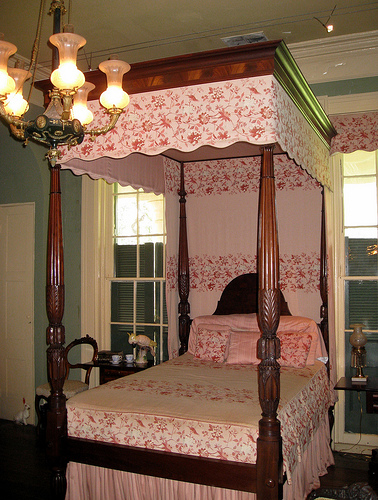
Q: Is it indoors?
A: Yes, it is indoors.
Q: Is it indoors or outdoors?
A: It is indoors.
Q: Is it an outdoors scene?
A: No, it is indoors.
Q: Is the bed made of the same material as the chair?
A: Yes, both the bed and the chair are made of wood.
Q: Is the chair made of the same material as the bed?
A: Yes, both the chair and the bed are made of wood.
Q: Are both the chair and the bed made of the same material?
A: Yes, both the chair and the bed are made of wood.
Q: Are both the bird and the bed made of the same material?
A: No, the bird is made of glass and the bed is made of wood.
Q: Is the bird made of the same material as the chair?
A: No, the bird is made of glass and the chair is made of wood.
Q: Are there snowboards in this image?
A: No, there are no snowboards.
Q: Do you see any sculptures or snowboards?
A: No, there are no snowboards or sculptures.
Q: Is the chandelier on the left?
A: Yes, the chandelier is on the left of the image.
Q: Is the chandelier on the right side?
A: No, the chandelier is on the left of the image.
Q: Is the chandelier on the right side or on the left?
A: The chandelier is on the left of the image.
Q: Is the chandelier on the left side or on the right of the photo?
A: The chandelier is on the left of the image.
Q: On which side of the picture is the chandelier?
A: The chandelier is on the left of the image.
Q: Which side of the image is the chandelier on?
A: The chandelier is on the left of the image.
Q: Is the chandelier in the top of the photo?
A: Yes, the chandelier is in the top of the image.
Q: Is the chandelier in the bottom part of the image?
A: No, the chandelier is in the top of the image.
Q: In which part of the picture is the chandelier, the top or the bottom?
A: The chandelier is in the top of the image.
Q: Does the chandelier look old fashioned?
A: Yes, the chandelier is old fashioned.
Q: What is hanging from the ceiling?
A: The chandelier is hanging from the ceiling.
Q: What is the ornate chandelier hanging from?
A: The chandelier is hanging from the ceiling.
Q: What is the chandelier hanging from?
A: The chandelier is hanging from the ceiling.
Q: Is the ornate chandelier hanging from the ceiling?
A: Yes, the chandelier is hanging from the ceiling.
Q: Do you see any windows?
A: Yes, there is a window.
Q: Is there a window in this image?
A: Yes, there is a window.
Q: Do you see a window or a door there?
A: Yes, there is a window.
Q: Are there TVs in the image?
A: No, there are no tvs.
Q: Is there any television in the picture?
A: No, there are no televisions.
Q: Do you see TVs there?
A: No, there are no tvs.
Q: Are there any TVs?
A: No, there are no tvs.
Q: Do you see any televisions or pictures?
A: No, there are no televisions or pictures.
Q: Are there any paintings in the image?
A: No, there are no paintings.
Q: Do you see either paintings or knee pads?
A: No, there are no paintings or knee pads.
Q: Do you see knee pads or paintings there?
A: No, there are no paintings or knee pads.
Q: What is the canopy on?
A: The canopy is on the bed.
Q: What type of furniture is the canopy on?
A: The canopy is on the bed.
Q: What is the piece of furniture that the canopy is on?
A: The piece of furniture is a bed.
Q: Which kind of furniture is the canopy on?
A: The canopy is on the bed.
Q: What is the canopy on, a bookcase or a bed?
A: The canopy is on a bed.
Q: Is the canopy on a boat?
A: No, the canopy is on a bed.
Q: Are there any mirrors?
A: No, there are no mirrors.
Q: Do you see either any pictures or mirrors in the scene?
A: No, there are no mirrors or pictures.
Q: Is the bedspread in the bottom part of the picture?
A: Yes, the bedspread is in the bottom of the image.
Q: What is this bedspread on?
A: The bedspread is on the bed.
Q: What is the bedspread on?
A: The bedspread is on the bed.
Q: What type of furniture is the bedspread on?
A: The bedspread is on the bed.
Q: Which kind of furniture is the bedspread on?
A: The bedspread is on the bed.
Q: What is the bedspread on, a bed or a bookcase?
A: The bedspread is on a bed.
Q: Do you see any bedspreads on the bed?
A: Yes, there is a bedspread on the bed.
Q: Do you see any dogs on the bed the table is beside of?
A: No, there is a bedspread on the bed.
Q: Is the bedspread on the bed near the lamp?
A: Yes, the bedspread is on the bed.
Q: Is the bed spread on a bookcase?
A: No, the bed spread is on the bed.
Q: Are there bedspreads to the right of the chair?
A: Yes, there is a bedspread to the right of the chair.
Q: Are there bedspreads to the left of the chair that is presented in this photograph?
A: No, the bedspread is to the right of the chair.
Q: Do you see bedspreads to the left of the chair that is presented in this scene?
A: No, the bedspread is to the right of the chair.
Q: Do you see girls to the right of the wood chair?
A: No, there is a bedspread to the right of the chair.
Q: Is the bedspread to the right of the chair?
A: Yes, the bedspread is to the right of the chair.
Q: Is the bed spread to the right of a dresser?
A: No, the bed spread is to the right of the chair.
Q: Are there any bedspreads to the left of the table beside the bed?
A: Yes, there is a bedspread to the left of the table.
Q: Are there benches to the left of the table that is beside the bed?
A: No, there is a bedspread to the left of the table.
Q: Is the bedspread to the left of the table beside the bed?
A: Yes, the bedspread is to the left of the table.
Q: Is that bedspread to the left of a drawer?
A: No, the bedspread is to the left of the table.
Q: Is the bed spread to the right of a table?
A: No, the bed spread is to the left of a table.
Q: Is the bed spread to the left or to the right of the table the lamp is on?
A: The bed spread is to the left of the table.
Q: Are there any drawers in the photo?
A: No, there are no drawers.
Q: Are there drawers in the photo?
A: No, there are no drawers.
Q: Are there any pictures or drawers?
A: No, there are no drawers or pictures.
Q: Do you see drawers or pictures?
A: No, there are no drawers or pictures.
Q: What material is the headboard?
A: The headboard is made of wood.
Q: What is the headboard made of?
A: The headboard is made of wood.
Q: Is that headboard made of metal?
A: No, the headboard is made of wood.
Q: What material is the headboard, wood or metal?
A: The headboard is made of wood.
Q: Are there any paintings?
A: No, there are no paintings.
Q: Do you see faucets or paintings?
A: No, there are no paintings or faucets.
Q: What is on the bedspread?
A: The flowers are on the bedspread.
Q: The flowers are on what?
A: The flowers are on the bedspread.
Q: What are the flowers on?
A: The flowers are on the bedspread.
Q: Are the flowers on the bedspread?
A: Yes, the flowers are on the bedspread.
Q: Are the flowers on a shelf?
A: No, the flowers are on the bedspread.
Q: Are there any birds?
A: Yes, there is a bird.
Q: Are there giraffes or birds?
A: Yes, there is a bird.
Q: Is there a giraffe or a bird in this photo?
A: Yes, there is a bird.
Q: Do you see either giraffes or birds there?
A: Yes, there is a bird.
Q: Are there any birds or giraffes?
A: Yes, there is a bird.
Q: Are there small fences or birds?
A: Yes, there is a small bird.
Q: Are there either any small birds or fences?
A: Yes, there is a small bird.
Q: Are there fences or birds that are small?
A: Yes, the bird is small.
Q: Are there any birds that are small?
A: Yes, there is a small bird.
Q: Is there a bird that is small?
A: Yes, there is a bird that is small.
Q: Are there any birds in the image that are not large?
A: Yes, there is a small bird.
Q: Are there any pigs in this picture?
A: No, there are no pigs.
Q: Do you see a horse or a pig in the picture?
A: No, there are no pigs or horses.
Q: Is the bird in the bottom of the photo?
A: Yes, the bird is in the bottom of the image.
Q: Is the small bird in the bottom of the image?
A: Yes, the bird is in the bottom of the image.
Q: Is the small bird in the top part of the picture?
A: No, the bird is in the bottom of the image.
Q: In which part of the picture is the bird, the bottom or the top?
A: The bird is in the bottom of the image.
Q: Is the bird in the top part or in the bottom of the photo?
A: The bird is in the bottom of the image.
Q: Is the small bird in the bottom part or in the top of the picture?
A: The bird is in the bottom of the image.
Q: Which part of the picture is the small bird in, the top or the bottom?
A: The bird is in the bottom of the image.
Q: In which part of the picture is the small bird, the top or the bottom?
A: The bird is in the bottom of the image.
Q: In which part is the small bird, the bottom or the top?
A: The bird is in the bottom of the image.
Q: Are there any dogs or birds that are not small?
A: No, there is a bird but it is small.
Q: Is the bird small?
A: Yes, the bird is small.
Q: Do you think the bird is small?
A: Yes, the bird is small.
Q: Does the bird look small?
A: Yes, the bird is small.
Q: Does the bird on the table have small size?
A: Yes, the bird is small.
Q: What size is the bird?
A: The bird is small.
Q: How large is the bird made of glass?
A: The bird is small.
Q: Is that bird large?
A: No, the bird is small.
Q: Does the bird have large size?
A: No, the bird is small.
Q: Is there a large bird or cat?
A: No, there is a bird but it is small.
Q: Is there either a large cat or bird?
A: No, there is a bird but it is small.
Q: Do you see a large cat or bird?
A: No, there is a bird but it is small.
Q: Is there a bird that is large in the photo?
A: No, there is a bird but it is small.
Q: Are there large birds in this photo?
A: No, there is a bird but it is small.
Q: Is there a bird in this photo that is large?
A: No, there is a bird but it is small.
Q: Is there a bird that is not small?
A: No, there is a bird but it is small.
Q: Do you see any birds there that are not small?
A: No, there is a bird but it is small.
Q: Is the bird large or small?
A: The bird is small.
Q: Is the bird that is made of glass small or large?
A: The bird is small.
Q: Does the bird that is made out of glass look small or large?
A: The bird is small.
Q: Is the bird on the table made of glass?
A: Yes, the bird is made of glass.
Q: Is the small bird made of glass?
A: Yes, the bird is made of glass.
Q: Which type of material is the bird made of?
A: The bird is made of glass.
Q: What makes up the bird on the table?
A: The bird is made of glass.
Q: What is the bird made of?
A: The bird is made of glass.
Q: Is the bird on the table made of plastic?
A: No, the bird is made of glass.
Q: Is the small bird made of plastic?
A: No, the bird is made of glass.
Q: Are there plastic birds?
A: No, there is a bird but it is made of glass.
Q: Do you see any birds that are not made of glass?
A: No, there is a bird but it is made of glass.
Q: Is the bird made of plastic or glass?
A: The bird is made of glass.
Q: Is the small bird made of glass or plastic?
A: The bird is made of glass.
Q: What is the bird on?
A: The bird is on the table.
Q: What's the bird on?
A: The bird is on the table.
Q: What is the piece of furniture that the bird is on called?
A: The piece of furniture is a table.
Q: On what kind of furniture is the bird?
A: The bird is on the table.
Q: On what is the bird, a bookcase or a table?
A: The bird is on a table.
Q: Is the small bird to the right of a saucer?
A: Yes, the bird is to the right of a saucer.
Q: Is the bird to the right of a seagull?
A: No, the bird is to the right of a saucer.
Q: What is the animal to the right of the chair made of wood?
A: The animal is a bird.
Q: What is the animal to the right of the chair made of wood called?
A: The animal is a bird.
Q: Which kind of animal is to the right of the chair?
A: The animal is a bird.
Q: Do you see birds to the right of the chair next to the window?
A: Yes, there is a bird to the right of the chair.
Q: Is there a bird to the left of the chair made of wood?
A: No, the bird is to the right of the chair.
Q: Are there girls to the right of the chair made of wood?
A: No, there is a bird to the right of the chair.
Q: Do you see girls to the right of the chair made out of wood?
A: No, there is a bird to the right of the chair.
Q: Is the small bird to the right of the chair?
A: Yes, the bird is to the right of the chair.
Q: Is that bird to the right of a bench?
A: No, the bird is to the right of the chair.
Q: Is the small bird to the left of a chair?
A: No, the bird is to the right of a chair.